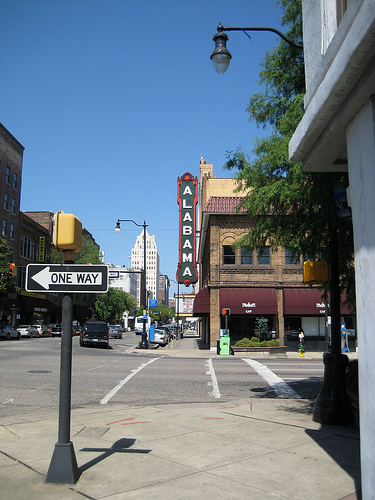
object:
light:
[209, 23, 232, 73]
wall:
[279, 0, 375, 500]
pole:
[45, 292, 81, 483]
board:
[175, 172, 198, 287]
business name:
[182, 185, 192, 277]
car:
[78, 320, 111, 348]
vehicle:
[146, 327, 170, 346]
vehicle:
[16, 325, 40, 339]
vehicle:
[31, 325, 52, 337]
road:
[0, 316, 358, 500]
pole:
[225, 24, 350, 422]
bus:
[134, 315, 151, 335]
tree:
[220, 0, 370, 401]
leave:
[223, 0, 357, 311]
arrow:
[30, 266, 102, 291]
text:
[49, 271, 101, 284]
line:
[204, 359, 221, 399]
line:
[241, 355, 300, 399]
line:
[99, 356, 160, 404]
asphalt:
[0, 325, 345, 424]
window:
[222, 242, 239, 267]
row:
[218, 242, 327, 272]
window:
[240, 246, 257, 268]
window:
[255, 248, 273, 267]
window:
[286, 244, 302, 267]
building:
[193, 153, 355, 348]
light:
[80, 333, 84, 337]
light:
[107, 329, 110, 338]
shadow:
[250, 375, 365, 500]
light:
[222, 308, 230, 316]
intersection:
[3, 342, 200, 405]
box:
[217, 336, 234, 355]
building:
[104, 227, 169, 320]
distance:
[96, 222, 179, 328]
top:
[133, 227, 157, 248]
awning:
[192, 289, 359, 317]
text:
[241, 301, 257, 314]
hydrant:
[298, 329, 306, 356]